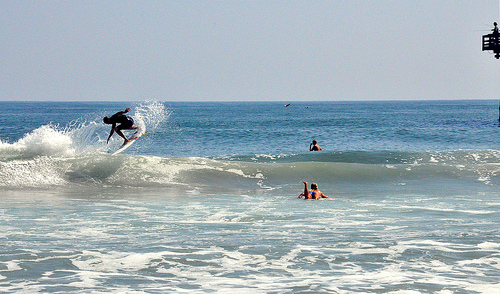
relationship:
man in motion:
[103, 107, 141, 144] [115, 128, 153, 153]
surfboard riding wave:
[110, 127, 145, 156] [81, 123, 168, 162]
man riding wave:
[103, 107, 141, 144] [81, 123, 168, 162]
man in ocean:
[309, 139, 322, 152] [11, 102, 498, 283]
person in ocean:
[296, 175, 325, 204] [11, 102, 498, 283]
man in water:
[305, 137, 321, 157] [5, 100, 499, 290]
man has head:
[101, 114, 141, 144] [102, 116, 113, 121]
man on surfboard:
[101, 114, 141, 144] [109, 127, 146, 155]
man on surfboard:
[103, 107, 141, 144] [109, 127, 146, 155]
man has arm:
[103, 107, 141, 144] [118, 108, 135, 115]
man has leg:
[103, 107, 141, 144] [114, 125, 126, 143]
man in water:
[309, 139, 322, 152] [5, 100, 499, 290]